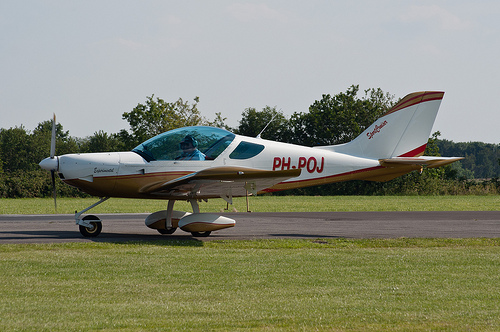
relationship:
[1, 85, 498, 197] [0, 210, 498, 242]
trees growing runway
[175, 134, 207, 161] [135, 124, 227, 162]
pilot sitting cockpit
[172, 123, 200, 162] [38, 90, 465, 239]
pilot on plane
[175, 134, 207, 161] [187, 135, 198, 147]
pilot wearing headphones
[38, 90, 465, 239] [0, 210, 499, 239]
plane on pavement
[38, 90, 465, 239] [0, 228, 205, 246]
plane casting shadows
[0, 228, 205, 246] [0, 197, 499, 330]
shadows on ground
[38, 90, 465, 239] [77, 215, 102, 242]
plane has wheel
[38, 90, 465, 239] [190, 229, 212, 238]
plane has wheel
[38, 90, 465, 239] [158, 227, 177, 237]
plane has wheel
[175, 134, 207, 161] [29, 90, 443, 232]
pilot in plane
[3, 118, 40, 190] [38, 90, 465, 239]
bushes growing behind plane